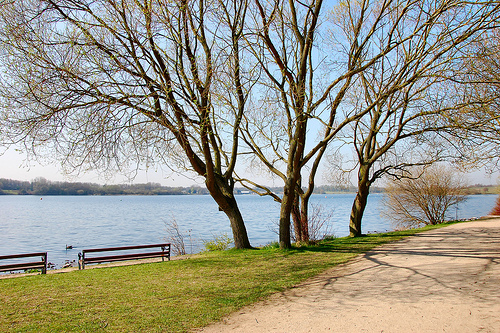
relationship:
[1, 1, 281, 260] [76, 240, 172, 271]
tree near bench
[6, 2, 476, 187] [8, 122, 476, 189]
sky with cloud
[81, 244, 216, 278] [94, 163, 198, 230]
bench near water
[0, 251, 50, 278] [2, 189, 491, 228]
bench near water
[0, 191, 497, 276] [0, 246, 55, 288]
water in front of bench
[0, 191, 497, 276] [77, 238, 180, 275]
water in front of bench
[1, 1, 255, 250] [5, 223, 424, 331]
tree in grassy area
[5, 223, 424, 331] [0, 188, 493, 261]
grassy area near water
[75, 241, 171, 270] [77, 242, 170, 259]
bench has gape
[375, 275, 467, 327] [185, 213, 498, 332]
sand covering floor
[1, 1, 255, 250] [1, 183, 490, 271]
tree beside lake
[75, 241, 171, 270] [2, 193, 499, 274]
bench beside lake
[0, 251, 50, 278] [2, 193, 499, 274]
bench beside lake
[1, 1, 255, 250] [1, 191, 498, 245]
tree far from lake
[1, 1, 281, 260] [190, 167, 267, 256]
tree has trunk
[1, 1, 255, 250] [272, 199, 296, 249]
tree has trunk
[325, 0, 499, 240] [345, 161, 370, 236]
tree has trunk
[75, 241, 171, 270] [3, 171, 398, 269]
bench sitting near lake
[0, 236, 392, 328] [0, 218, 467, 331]
dirt in grass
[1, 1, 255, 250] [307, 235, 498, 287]
tree casting shadow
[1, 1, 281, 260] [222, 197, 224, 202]
tree has bark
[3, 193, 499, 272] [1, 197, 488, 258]
waves in water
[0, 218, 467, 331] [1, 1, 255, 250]
grass with tree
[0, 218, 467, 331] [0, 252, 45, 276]
grass with bench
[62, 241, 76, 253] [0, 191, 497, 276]
bird in water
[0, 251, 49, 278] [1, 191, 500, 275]
bench in front of lake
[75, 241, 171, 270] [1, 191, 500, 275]
bench in front of lake